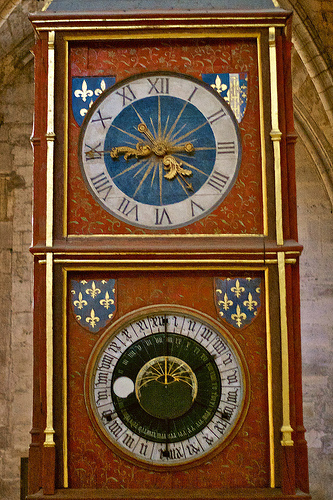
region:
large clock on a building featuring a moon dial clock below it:
[17, 7, 310, 497]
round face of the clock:
[79, 69, 242, 231]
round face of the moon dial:
[93, 309, 249, 465]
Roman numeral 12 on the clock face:
[141, 76, 176, 95]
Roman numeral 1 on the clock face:
[185, 82, 201, 104]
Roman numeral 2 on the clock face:
[200, 102, 232, 125]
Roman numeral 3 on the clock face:
[215, 138, 240, 158]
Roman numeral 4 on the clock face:
[204, 166, 230, 195]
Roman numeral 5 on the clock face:
[185, 197, 207, 216]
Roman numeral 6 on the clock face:
[147, 202, 174, 225]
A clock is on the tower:
[21, 3, 313, 252]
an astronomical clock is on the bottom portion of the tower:
[24, 248, 299, 494]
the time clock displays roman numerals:
[71, 50, 265, 225]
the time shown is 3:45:
[85, 125, 203, 195]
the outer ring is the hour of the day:
[91, 314, 238, 455]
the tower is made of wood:
[24, 2, 308, 495]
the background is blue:
[114, 100, 210, 193]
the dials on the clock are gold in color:
[106, 112, 203, 194]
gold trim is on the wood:
[34, 23, 68, 258]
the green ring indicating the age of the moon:
[113, 338, 215, 431]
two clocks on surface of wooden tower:
[44, 22, 283, 498]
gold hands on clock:
[104, 120, 208, 198]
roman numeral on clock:
[141, 73, 176, 97]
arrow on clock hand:
[178, 176, 199, 195]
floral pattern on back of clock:
[74, 49, 133, 68]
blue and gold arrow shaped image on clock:
[198, 68, 257, 120]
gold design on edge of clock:
[42, 31, 65, 245]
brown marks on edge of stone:
[299, 17, 330, 126]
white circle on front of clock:
[108, 373, 136, 402]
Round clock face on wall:
[79, 72, 240, 228]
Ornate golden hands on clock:
[107, 129, 195, 191]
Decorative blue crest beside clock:
[75, 75, 109, 119]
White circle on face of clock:
[113, 376, 133, 398]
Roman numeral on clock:
[185, 440, 198, 457]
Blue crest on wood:
[214, 277, 263, 327]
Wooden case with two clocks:
[28, 6, 307, 499]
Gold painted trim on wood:
[61, 268, 71, 488]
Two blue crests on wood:
[67, 273, 259, 331]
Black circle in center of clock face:
[114, 331, 219, 442]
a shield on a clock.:
[195, 66, 254, 122]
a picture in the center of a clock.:
[128, 351, 202, 421]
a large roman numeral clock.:
[79, 302, 252, 471]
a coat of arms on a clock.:
[66, 67, 122, 125]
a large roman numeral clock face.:
[76, 64, 244, 233]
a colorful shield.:
[65, 69, 120, 128]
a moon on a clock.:
[109, 369, 136, 403]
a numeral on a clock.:
[159, 305, 181, 331]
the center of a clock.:
[130, 353, 199, 418]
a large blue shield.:
[206, 269, 267, 328]